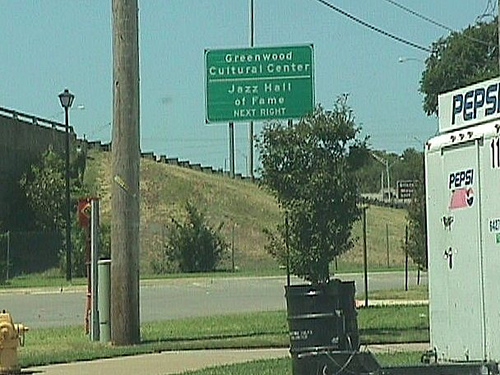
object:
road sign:
[201, 42, 318, 126]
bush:
[157, 203, 235, 271]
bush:
[58, 210, 120, 275]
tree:
[253, 90, 377, 287]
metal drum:
[279, 283, 357, 374]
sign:
[198, 43, 321, 125]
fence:
[176, 159, 248, 181]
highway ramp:
[141, 145, 293, 247]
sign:
[447, 169, 476, 214]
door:
[425, 136, 480, 365]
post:
[107, 2, 152, 347]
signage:
[426, 81, 496, 125]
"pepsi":
[449, 83, 499, 127]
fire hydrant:
[0, 307, 30, 373]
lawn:
[1, 283, 498, 373]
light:
[57, 89, 74, 109]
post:
[66, 110, 72, 286]